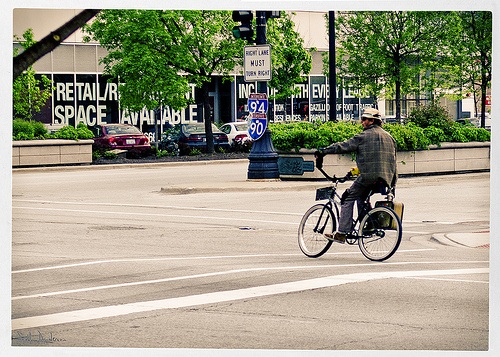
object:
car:
[90, 123, 152, 156]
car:
[174, 122, 230, 155]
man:
[307, 110, 401, 246]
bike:
[296, 149, 404, 263]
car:
[217, 121, 258, 148]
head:
[360, 107, 383, 129]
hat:
[361, 106, 381, 120]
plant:
[268, 120, 319, 150]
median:
[264, 140, 492, 182]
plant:
[455, 122, 492, 143]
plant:
[404, 104, 452, 143]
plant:
[385, 121, 431, 152]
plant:
[300, 116, 363, 161]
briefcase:
[373, 201, 405, 231]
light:
[231, 25, 242, 38]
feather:
[373, 113, 380, 117]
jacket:
[319, 125, 400, 189]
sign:
[247, 92, 269, 119]